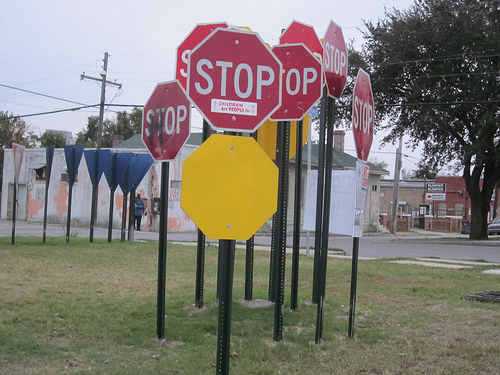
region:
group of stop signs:
[137, 20, 375, 340]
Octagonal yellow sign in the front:
[177, 133, 277, 372]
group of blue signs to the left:
[42, 145, 152, 240]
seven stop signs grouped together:
[144, 20, 375, 343]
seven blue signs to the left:
[43, 143, 153, 243]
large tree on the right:
[313, 1, 498, 241]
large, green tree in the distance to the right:
[312, 0, 498, 242]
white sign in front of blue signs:
[11, 144, 21, 245]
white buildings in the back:
[3, 133, 390, 233]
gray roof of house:
[118, 131, 383, 172]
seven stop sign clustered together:
[125, 14, 402, 176]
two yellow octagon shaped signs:
[184, 102, 319, 253]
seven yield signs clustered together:
[7, 133, 142, 198]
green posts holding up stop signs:
[140, 113, 377, 365]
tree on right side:
[367, 8, 498, 230]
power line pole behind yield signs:
[72, 48, 129, 234]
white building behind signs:
[5, 138, 385, 249]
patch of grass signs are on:
[6, 228, 490, 374]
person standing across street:
[132, 185, 141, 230]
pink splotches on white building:
[14, 169, 209, 236]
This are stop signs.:
[140, 5, 390, 148]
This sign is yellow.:
[154, 30, 419, 157]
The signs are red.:
[151, 17, 374, 139]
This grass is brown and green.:
[20, 267, 105, 367]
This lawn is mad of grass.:
[17, 245, 147, 361]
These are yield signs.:
[32, 140, 157, 190]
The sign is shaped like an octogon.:
[190, 25, 296, 130]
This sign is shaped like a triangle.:
[80, 145, 117, 181]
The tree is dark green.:
[380, 28, 496, 149]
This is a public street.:
[336, 168, 486, 235]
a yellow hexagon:
[176, 135, 280, 243]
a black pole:
[217, 263, 234, 370]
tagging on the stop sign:
[143, 109, 169, 148]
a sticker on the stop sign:
[208, 96, 260, 116]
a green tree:
[450, 29, 497, 239]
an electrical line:
[3, 77, 93, 107]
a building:
[395, 169, 460, 219]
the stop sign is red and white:
[321, 25, 348, 96]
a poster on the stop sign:
[353, 163, 371, 235]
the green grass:
[16, 234, 153, 364]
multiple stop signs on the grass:
[21, 15, 482, 275]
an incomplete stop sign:
[155, 120, 301, 245]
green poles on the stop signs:
[161, 127, 366, 357]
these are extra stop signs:
[180, 25, 391, 145]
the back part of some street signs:
[48, 126, 156, 198]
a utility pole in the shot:
[59, 49, 130, 136]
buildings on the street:
[368, 155, 498, 260]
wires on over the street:
[4, 72, 137, 122]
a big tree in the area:
[383, 3, 498, 238]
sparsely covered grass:
[39, 238, 476, 371]